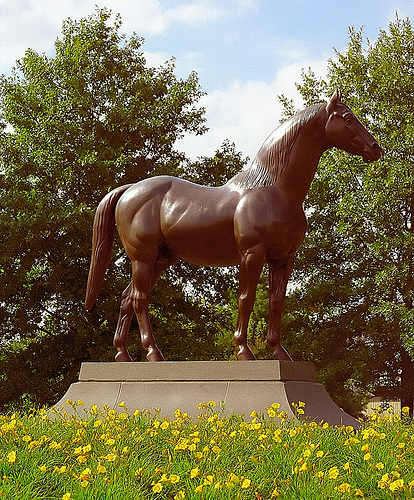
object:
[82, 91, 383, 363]
horse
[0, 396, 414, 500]
field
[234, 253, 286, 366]
leg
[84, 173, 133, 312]
tail